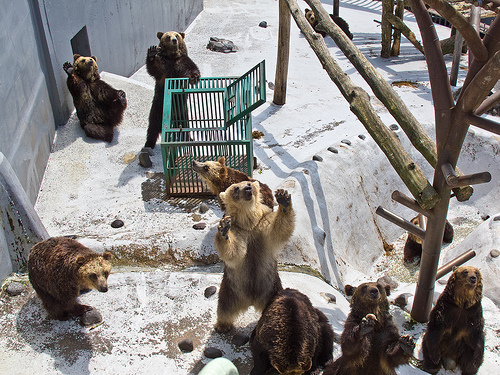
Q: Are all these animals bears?
A: Yes, all the animals are bears.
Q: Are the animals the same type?
A: Yes, all the animals are bears.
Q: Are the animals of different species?
A: No, all the animals are bears.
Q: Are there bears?
A: Yes, there is a bear.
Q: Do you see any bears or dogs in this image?
A: Yes, there is a bear.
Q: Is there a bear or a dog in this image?
A: Yes, there is a bear.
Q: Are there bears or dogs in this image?
A: Yes, there is a bear.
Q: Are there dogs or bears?
A: Yes, there is a bear.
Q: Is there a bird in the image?
A: No, there are no birds.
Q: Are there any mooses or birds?
A: No, there are no birds or mooses.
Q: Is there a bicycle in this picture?
A: No, there are no bicycles.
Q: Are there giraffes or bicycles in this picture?
A: No, there are no bicycles or giraffes.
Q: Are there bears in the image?
A: Yes, there is a bear.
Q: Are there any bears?
A: Yes, there is a bear.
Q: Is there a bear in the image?
A: Yes, there is a bear.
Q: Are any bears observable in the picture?
A: Yes, there is a bear.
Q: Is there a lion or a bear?
A: Yes, there is a bear.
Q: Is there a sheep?
A: No, there is no sheep.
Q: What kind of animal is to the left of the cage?
A: The animal is a bear.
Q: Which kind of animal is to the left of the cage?
A: The animal is a bear.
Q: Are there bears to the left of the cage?
A: Yes, there is a bear to the left of the cage.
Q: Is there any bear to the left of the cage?
A: Yes, there is a bear to the left of the cage.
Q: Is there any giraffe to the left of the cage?
A: No, there is a bear to the left of the cage.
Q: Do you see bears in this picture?
A: Yes, there is a bear.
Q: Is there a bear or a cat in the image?
A: Yes, there is a bear.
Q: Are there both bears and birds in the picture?
A: No, there is a bear but no birds.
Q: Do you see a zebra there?
A: No, there are no zebras.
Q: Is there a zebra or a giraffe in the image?
A: No, there are no zebras or giraffes.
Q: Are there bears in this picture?
A: Yes, there is a bear.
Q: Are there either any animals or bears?
A: Yes, there is a bear.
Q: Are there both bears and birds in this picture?
A: No, there is a bear but no birds.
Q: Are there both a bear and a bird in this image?
A: No, there is a bear but no birds.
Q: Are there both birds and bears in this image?
A: No, there is a bear but no birds.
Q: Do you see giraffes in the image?
A: No, there are no giraffes.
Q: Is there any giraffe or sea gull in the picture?
A: No, there are no giraffes or seagulls.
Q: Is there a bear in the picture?
A: Yes, there is a bear.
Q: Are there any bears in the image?
A: Yes, there is a bear.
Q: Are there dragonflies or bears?
A: Yes, there is a bear.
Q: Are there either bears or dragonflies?
A: Yes, there is a bear.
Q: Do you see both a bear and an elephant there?
A: No, there is a bear but no elephants.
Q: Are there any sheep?
A: No, there are no sheep.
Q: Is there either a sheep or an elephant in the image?
A: No, there are no sheep or elephants.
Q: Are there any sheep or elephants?
A: No, there are no sheep or elephants.